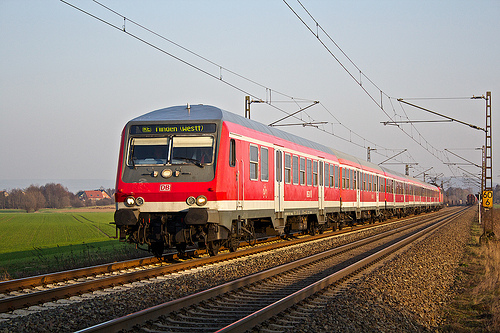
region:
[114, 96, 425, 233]
red light rail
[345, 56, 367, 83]
white clouds in blue sky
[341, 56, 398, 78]
white clouds in blue sky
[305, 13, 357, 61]
white clouds in blue sky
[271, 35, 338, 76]
white clouds in blue sky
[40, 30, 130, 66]
white clouds in blue sky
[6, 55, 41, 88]
white clouds in blue sky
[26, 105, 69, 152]
white clouds in blue sky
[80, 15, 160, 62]
white clouds in blue sky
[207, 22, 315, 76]
white clouds in blue sky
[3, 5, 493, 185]
clear light blue sky over train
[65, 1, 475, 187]
connected parallel wires over train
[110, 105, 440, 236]
red passenger train with white stripes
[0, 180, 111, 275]
planted field in front of house with trees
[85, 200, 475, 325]
empty track next to train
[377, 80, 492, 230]
wire attached to pole shaped like narrowing ladder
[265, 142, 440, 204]
white doors between dark windows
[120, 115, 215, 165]
train information over train windows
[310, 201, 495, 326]
weeds growing on side next to gravel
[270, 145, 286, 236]
recessed lower panel with step below door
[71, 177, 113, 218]
a house in the distance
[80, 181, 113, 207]
a house in the distance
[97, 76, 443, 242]
the train is red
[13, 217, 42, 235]
short green and brown grass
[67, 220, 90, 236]
short green and brown grass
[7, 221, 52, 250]
short green and brown grass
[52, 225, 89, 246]
short green and brown grass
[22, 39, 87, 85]
white clouds in blue sky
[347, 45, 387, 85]
white clouds in blue sky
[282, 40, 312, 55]
white clouds in blue sky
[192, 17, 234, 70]
white clouds in blue sky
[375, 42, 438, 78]
white clouds in blue sky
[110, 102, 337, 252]
a red and white train car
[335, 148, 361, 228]
a train passenger car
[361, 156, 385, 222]
a train passenger car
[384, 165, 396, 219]
a train passenger car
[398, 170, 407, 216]
a train passenger car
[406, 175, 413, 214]
a train passenger car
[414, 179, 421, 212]
a train passenger car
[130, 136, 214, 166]
a train front windshield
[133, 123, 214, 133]
electronic train destination sign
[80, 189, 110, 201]
a large brown roofed building in distance